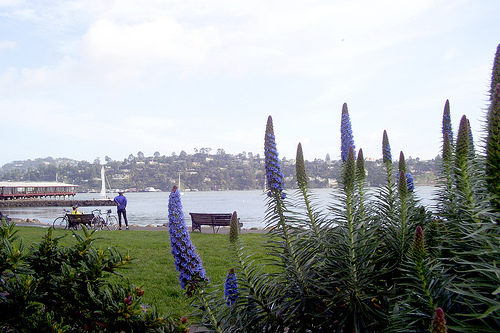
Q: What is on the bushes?
A: Flowers.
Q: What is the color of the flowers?
A: Purple.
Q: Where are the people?
A: By the bench.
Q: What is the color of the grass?
A: Green.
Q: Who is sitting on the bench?
A: A person.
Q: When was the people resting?
A: Daytime.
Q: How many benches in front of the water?
A: Two.